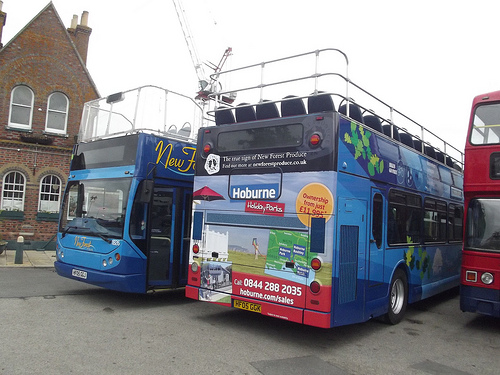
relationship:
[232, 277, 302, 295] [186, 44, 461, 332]
white numbers on back of bus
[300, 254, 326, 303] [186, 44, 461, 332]
lights on back of bus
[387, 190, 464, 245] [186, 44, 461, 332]
window along side of bus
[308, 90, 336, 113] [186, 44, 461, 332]
seat on top of bus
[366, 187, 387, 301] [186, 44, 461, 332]
blue door on side of bus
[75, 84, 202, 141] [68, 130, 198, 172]
windshield on top deck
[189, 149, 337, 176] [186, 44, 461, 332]
advertisement on bus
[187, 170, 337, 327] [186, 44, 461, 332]
advertisement on bus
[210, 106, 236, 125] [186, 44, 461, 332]
seat on bus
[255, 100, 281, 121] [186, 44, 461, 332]
seat on bus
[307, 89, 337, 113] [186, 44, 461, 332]
seat on bus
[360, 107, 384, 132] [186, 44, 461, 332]
seat on bus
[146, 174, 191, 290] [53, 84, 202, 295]
door to bus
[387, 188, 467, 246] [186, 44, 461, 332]
window on bus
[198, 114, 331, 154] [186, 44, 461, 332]
brake light on bus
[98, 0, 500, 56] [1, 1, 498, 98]
clouds in sky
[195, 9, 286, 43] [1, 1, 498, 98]
clouds in sky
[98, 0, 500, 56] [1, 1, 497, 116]
clouds in sky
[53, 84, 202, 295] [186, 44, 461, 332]
bus next to bus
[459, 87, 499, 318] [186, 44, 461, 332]
bus next to bus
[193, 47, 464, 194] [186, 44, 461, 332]
top of bus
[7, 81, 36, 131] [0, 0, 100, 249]
window on front of building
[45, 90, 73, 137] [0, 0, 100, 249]
window on front of building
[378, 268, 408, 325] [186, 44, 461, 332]
black tire attached to bus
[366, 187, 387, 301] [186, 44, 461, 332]
blue door on bus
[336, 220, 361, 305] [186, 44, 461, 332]
vent on back of bus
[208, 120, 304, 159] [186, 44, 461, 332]
back window on bus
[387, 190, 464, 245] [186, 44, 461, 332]
window on side of bus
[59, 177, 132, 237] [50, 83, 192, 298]
large windshield on front of bus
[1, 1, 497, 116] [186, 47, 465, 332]
sky above bus